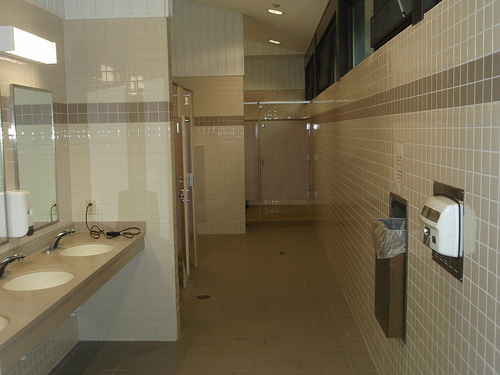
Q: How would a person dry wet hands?
A: Hand dryer.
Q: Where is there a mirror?
A: Above the sink.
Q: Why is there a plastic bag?
A: For trash.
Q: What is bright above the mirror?
A: Light.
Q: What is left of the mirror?
A: Soap dispenser.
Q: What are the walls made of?
A: Tile.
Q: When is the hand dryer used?
A: After washing.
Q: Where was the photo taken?
A: In a room.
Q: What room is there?
A: Bathroom.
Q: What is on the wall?
A: White object to dry hands.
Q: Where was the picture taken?
A: Bathroom.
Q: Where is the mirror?
A: Left side.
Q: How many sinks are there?
A: Two.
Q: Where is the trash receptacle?
A: Right side.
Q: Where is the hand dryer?
A: Right side.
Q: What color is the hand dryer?
A: White.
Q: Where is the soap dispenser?
A: Between the sinks.